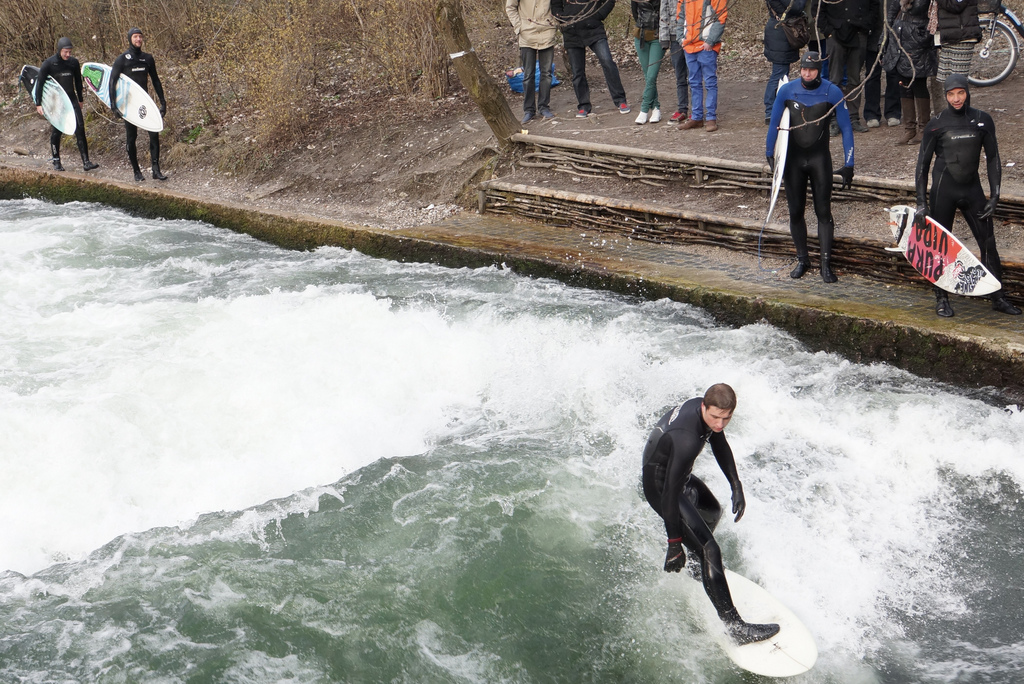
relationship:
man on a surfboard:
[626, 356, 810, 676] [684, 549, 823, 677]